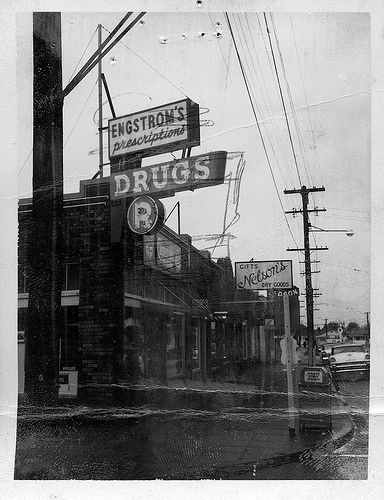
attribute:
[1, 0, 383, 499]
photograph — damaged, folded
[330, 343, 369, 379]
car — parked, white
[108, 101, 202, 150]
sign — old, rectangular, for business, neon, black writing, white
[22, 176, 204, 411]
building — brick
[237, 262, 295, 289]
sign — here, neon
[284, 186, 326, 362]
pole — tall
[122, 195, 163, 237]
sign — round, lettered, white lettered r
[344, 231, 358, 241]
light — off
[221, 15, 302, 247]
wire — black, power line